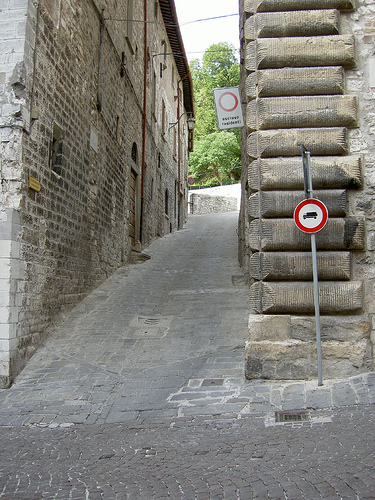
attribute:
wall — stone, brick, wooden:
[243, 1, 374, 385]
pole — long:
[298, 148, 326, 388]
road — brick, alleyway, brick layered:
[4, 212, 374, 498]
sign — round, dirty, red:
[293, 199, 329, 235]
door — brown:
[124, 170, 142, 255]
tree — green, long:
[191, 43, 244, 185]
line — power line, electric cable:
[175, 6, 243, 24]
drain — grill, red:
[266, 404, 313, 424]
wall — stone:
[13, 5, 194, 400]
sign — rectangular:
[213, 86, 250, 128]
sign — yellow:
[29, 169, 44, 198]